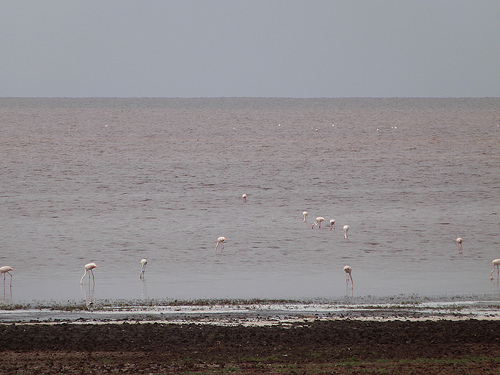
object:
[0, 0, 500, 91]
clouds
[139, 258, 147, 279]
birds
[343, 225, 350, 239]
birds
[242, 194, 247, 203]
birds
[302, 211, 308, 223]
birds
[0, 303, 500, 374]
ground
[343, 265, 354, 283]
birds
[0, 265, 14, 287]
swan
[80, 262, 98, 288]
swan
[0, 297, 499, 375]
beach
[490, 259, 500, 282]
swan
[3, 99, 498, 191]
water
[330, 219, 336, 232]
birds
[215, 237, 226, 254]
birds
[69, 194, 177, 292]
these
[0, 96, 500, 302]
ocean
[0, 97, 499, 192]
brown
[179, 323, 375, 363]
sandy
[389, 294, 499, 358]
rocky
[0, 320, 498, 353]
brown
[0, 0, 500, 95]
blue sky